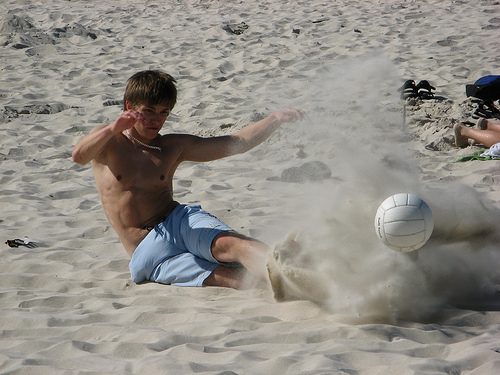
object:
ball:
[373, 193, 436, 254]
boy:
[69, 69, 309, 291]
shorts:
[128, 204, 244, 288]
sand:
[3, 11, 336, 56]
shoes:
[397, 79, 435, 100]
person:
[453, 117, 500, 149]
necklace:
[126, 129, 161, 151]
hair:
[124, 69, 179, 111]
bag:
[466, 75, 500, 103]